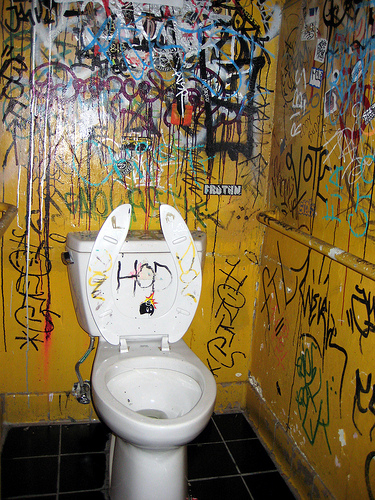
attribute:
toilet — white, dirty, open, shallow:
[57, 191, 222, 500]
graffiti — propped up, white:
[76, 198, 205, 326]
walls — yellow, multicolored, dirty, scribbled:
[0, 0, 369, 435]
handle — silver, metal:
[56, 249, 79, 270]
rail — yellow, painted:
[250, 205, 374, 282]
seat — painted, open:
[75, 195, 209, 347]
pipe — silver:
[64, 334, 94, 410]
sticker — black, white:
[200, 174, 247, 204]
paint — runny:
[13, 9, 269, 225]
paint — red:
[35, 228, 65, 384]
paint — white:
[37, 4, 290, 81]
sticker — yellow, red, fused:
[170, 100, 193, 127]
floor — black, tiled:
[4, 412, 295, 497]